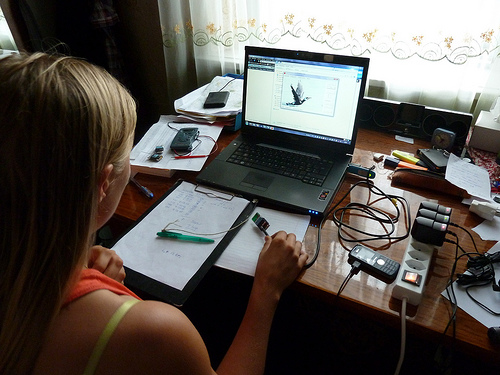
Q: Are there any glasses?
A: No, there are no glasses.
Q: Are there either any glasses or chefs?
A: No, there are no glasses or chefs.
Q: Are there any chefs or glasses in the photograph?
A: No, there are no glasses or chefs.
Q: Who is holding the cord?
A: The girl is holding the cord.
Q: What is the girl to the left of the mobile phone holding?
A: The girl is holding the wire.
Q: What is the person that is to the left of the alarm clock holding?
A: The girl is holding the wire.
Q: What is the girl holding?
A: The girl is holding the wire.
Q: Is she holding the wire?
A: Yes, the girl is holding the wire.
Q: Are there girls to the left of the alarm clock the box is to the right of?
A: Yes, there is a girl to the left of the alarm clock.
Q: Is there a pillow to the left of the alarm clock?
A: No, there is a girl to the left of the alarm clock.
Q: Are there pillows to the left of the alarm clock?
A: No, there is a girl to the left of the alarm clock.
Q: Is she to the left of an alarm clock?
A: Yes, the girl is to the left of an alarm clock.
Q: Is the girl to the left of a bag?
A: No, the girl is to the left of an alarm clock.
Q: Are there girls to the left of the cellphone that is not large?
A: Yes, there is a girl to the left of the cellphone.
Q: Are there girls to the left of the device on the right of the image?
A: Yes, there is a girl to the left of the cellphone.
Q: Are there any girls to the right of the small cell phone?
A: No, the girl is to the left of the cellphone.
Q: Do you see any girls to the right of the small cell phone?
A: No, the girl is to the left of the cellphone.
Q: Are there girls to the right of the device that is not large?
A: No, the girl is to the left of the cellphone.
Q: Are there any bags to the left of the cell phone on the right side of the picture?
A: No, there is a girl to the left of the cell phone.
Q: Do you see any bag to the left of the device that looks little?
A: No, there is a girl to the left of the cell phone.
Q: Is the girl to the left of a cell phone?
A: Yes, the girl is to the left of a cell phone.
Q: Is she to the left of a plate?
A: No, the girl is to the left of a cell phone.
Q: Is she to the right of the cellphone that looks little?
A: No, the girl is to the left of the cellphone.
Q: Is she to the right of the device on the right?
A: No, the girl is to the left of the cellphone.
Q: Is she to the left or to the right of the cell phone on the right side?
A: The girl is to the left of the cellphone.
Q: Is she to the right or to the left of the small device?
A: The girl is to the left of the cellphone.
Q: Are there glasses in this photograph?
A: No, there are no glasses.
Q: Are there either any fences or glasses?
A: No, there are no glasses or fences.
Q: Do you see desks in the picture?
A: Yes, there is a desk.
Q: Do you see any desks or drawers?
A: Yes, there is a desk.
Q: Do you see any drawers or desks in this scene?
A: Yes, there is a desk.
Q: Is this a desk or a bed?
A: This is a desk.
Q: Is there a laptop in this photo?
A: Yes, there is a laptop.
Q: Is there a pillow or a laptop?
A: Yes, there is a laptop.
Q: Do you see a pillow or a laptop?
A: Yes, there is a laptop.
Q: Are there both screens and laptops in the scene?
A: Yes, there are both a laptop and a screen.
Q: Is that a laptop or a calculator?
A: That is a laptop.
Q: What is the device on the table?
A: The device is a laptop.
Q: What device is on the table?
A: The device is a laptop.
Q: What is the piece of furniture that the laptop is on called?
A: The piece of furniture is a table.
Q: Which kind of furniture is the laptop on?
A: The laptop is on the table.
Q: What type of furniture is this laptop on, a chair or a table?
A: The laptop is on a table.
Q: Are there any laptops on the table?
A: Yes, there is a laptop on the table.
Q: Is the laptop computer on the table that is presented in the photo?
A: Yes, the laptop computer is on the table.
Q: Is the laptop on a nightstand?
A: No, the laptop is on the table.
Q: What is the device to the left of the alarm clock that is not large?
A: The device is a laptop.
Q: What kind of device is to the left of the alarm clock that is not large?
A: The device is a laptop.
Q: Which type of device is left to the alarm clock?
A: The device is a laptop.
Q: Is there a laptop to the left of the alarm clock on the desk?
A: Yes, there is a laptop to the left of the alarm clock.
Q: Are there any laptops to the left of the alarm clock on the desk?
A: Yes, there is a laptop to the left of the alarm clock.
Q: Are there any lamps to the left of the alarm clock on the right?
A: No, there is a laptop to the left of the alarm clock.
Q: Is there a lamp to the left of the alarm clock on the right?
A: No, there is a laptop to the left of the alarm clock.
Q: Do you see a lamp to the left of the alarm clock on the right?
A: No, there is a laptop to the left of the alarm clock.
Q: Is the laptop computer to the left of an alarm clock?
A: Yes, the laptop computer is to the left of an alarm clock.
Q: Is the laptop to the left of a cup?
A: No, the laptop is to the left of an alarm clock.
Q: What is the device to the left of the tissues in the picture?
A: The device is a laptop.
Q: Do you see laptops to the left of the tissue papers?
A: Yes, there is a laptop to the left of the tissue papers.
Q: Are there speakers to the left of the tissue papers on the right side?
A: No, there is a laptop to the left of the tissues.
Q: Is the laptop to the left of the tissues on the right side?
A: Yes, the laptop is to the left of the tissues.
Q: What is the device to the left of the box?
A: The device is a laptop.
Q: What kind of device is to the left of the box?
A: The device is a laptop.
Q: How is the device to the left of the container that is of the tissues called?
A: The device is a laptop.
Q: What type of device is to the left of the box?
A: The device is a laptop.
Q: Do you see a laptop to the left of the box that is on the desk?
A: Yes, there is a laptop to the left of the box.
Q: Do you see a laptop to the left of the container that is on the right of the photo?
A: Yes, there is a laptop to the left of the box.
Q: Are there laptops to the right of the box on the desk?
A: No, the laptop is to the left of the box.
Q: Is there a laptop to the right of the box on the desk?
A: No, the laptop is to the left of the box.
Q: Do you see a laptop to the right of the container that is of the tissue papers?
A: No, the laptop is to the left of the box.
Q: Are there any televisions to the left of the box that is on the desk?
A: No, there is a laptop to the left of the box.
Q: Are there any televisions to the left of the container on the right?
A: No, there is a laptop to the left of the box.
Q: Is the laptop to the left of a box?
A: Yes, the laptop is to the left of a box.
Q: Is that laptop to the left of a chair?
A: No, the laptop is to the left of a box.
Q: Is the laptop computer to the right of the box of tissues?
A: No, the laptop computer is to the left of the box.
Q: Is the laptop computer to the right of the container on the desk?
A: No, the laptop computer is to the left of the box.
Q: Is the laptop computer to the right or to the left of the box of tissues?
A: The laptop computer is to the left of the box.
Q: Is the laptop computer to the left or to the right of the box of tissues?
A: The laptop computer is to the left of the box.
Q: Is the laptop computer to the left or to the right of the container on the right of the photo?
A: The laptop computer is to the left of the box.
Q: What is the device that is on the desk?
A: The device is a laptop.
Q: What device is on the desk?
A: The device is a laptop.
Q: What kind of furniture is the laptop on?
A: The laptop is on the desk.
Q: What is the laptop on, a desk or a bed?
A: The laptop is on a desk.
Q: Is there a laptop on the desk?
A: Yes, there is a laptop on the desk.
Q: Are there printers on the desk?
A: No, there is a laptop on the desk.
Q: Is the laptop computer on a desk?
A: Yes, the laptop computer is on a desk.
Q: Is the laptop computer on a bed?
A: No, the laptop computer is on a desk.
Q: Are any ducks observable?
A: Yes, there is a duck.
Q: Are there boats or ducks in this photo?
A: Yes, there is a duck.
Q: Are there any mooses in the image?
A: No, there are no mooses.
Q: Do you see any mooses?
A: No, there are no mooses.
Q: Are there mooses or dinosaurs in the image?
A: No, there are no mooses or dinosaurs.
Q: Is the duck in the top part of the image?
A: Yes, the duck is in the top of the image.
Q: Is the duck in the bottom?
A: No, the duck is in the top of the image.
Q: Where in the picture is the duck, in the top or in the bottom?
A: The duck is in the top of the image.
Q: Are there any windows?
A: Yes, there is a window.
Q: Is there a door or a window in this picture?
A: Yes, there is a window.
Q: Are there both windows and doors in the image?
A: No, there is a window but no doors.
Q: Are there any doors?
A: No, there are no doors.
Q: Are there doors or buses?
A: No, there are no doors or buses.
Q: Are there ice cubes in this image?
A: No, there are no ice cubes.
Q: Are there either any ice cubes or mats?
A: No, there are no ice cubes or mats.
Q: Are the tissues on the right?
A: Yes, the tissues are on the right of the image.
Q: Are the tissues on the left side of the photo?
A: No, the tissues are on the right of the image.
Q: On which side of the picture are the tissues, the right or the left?
A: The tissues are on the right of the image.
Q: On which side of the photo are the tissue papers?
A: The tissue papers are on the right of the image.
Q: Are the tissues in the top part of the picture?
A: Yes, the tissues are in the top of the image.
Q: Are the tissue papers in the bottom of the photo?
A: No, the tissue papers are in the top of the image.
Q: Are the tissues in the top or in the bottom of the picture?
A: The tissues are in the top of the image.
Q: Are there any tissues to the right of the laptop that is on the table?
A: Yes, there are tissues to the right of the laptop.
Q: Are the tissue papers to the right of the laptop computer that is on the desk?
A: Yes, the tissue papers are to the right of the laptop computer.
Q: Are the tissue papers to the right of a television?
A: No, the tissue papers are to the right of the laptop computer.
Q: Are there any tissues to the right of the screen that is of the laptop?
A: Yes, there are tissues to the right of the screen.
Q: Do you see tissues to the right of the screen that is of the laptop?
A: Yes, there are tissues to the right of the screen.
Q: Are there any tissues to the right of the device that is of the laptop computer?
A: Yes, there are tissues to the right of the screen.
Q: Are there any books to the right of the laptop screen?
A: No, there are tissues to the right of the screen.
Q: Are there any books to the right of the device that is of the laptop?
A: No, there are tissues to the right of the screen.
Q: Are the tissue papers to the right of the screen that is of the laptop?
A: Yes, the tissue papers are to the right of the screen.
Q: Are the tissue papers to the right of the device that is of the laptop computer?
A: Yes, the tissue papers are to the right of the screen.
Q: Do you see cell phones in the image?
A: Yes, there is a cell phone.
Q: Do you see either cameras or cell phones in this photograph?
A: Yes, there is a cell phone.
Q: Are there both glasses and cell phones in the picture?
A: No, there is a cell phone but no glasses.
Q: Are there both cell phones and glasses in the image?
A: No, there is a cell phone but no glasses.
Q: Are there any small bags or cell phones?
A: Yes, there is a small cell phone.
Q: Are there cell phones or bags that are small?
A: Yes, the cell phone is small.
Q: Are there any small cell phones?
A: Yes, there is a small cell phone.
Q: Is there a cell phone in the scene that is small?
A: Yes, there is a cell phone that is small.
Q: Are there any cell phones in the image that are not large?
A: Yes, there is a small cell phone.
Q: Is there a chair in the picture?
A: No, there are no chairs.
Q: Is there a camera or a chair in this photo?
A: No, there are no chairs or cameras.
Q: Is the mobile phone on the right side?
A: Yes, the mobile phone is on the right of the image.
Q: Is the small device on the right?
A: Yes, the mobile phone is on the right of the image.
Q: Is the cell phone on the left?
A: No, the cell phone is on the right of the image.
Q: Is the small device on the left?
A: No, the cell phone is on the right of the image.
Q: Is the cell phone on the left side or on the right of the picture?
A: The cell phone is on the right of the image.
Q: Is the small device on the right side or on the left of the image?
A: The cell phone is on the right of the image.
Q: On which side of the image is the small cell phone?
A: The mobile phone is on the right of the image.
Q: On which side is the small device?
A: The mobile phone is on the right of the image.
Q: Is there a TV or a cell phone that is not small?
A: No, there is a cell phone but it is small.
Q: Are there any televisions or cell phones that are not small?
A: No, there is a cell phone but it is small.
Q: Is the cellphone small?
A: Yes, the cellphone is small.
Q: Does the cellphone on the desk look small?
A: Yes, the cell phone is small.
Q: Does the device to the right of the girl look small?
A: Yes, the cell phone is small.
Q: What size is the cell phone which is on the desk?
A: The cellphone is small.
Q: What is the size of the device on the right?
A: The cellphone is small.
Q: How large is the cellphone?
A: The cellphone is small.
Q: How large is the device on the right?
A: The cellphone is small.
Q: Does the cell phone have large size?
A: No, the cell phone is small.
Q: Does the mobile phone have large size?
A: No, the mobile phone is small.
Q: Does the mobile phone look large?
A: No, the mobile phone is small.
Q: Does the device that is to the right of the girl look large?
A: No, the mobile phone is small.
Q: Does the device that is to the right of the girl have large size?
A: No, the mobile phone is small.